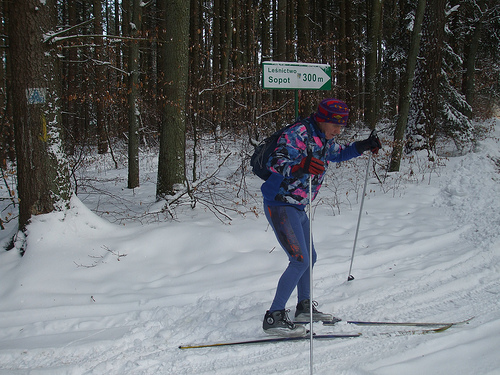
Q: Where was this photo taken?
A: On a ski slope.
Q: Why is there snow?
A: They are on a ski slope.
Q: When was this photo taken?
A: During winter.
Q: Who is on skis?
A: The person.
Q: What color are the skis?
A: Gray.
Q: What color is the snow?
A: White.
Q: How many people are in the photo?
A: One.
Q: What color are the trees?
A: Brown.